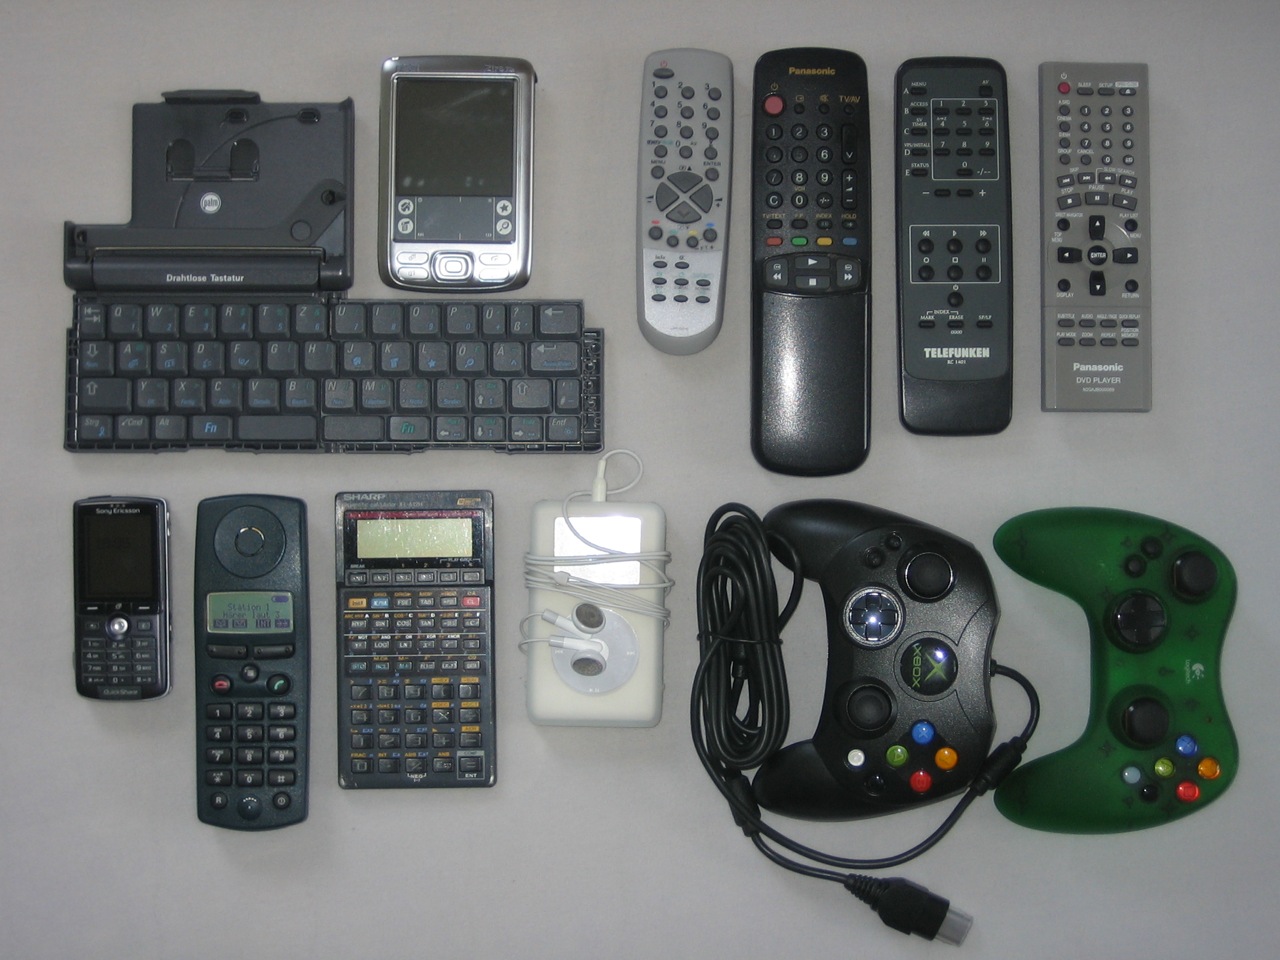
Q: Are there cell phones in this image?
A: Yes, there is a cell phone.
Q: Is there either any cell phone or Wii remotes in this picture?
A: Yes, there is a cell phone.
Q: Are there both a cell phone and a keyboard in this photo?
A: Yes, there are both a cell phone and a keyboard.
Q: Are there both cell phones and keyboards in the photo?
A: Yes, there are both a cell phone and a keyboard.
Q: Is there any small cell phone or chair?
A: Yes, there is a small cell phone.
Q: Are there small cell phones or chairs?
A: Yes, there is a small cell phone.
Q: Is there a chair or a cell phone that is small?
A: Yes, the cell phone is small.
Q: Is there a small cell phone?
A: Yes, there is a small cell phone.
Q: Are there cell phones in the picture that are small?
A: Yes, there is a cell phone that is small.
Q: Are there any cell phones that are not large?
A: Yes, there is a small cell phone.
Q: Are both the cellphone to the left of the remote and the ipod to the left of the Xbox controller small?
A: Yes, both the cell phone and the ipod are small.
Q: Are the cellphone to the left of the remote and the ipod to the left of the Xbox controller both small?
A: Yes, both the cell phone and the ipod are small.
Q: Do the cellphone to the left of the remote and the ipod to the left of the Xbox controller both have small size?
A: Yes, both the cell phone and the ipod are small.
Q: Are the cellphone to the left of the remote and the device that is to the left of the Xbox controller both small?
A: Yes, both the cell phone and the ipod are small.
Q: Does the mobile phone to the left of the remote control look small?
A: Yes, the mobile phone is small.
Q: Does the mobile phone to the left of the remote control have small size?
A: Yes, the mobile phone is small.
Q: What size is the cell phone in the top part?
A: The cellphone is small.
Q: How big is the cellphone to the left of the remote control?
A: The cell phone is small.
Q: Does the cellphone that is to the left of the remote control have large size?
A: No, the cellphone is small.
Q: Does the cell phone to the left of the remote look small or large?
A: The mobile phone is small.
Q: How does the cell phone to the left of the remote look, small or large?
A: The mobile phone is small.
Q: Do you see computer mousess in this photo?
A: No, there are no computer mousess.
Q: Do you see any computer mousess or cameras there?
A: No, there are no computer mousess or cameras.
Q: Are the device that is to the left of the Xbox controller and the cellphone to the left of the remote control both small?
A: Yes, both the ipod and the cellphone are small.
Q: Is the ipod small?
A: Yes, the ipod is small.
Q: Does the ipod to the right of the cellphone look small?
A: Yes, the ipod is small.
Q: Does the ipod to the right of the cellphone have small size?
A: Yes, the ipod is small.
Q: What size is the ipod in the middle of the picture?
A: The ipod is small.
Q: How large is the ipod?
A: The ipod is small.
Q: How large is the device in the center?
A: The ipod is small.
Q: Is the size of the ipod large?
A: No, the ipod is small.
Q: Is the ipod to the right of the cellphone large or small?
A: The ipod is small.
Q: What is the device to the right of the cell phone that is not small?
A: The device is an ipod.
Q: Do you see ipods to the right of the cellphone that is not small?
A: Yes, there is an ipod to the right of the mobile phone.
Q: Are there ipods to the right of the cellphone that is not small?
A: Yes, there is an ipod to the right of the mobile phone.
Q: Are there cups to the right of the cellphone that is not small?
A: No, there is an ipod to the right of the cell phone.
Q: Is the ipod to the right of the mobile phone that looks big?
A: Yes, the ipod is to the right of the cell phone.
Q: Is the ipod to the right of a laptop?
A: No, the ipod is to the right of the cell phone.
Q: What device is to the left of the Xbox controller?
A: The device is an ipod.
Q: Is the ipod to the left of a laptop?
A: No, the ipod is to the left of the Xbox controller.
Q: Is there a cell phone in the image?
A: Yes, there is a cell phone.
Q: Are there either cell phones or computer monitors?
A: Yes, there is a cell phone.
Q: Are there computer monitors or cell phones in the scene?
A: Yes, there is a cell phone.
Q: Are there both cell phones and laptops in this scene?
A: No, there is a cell phone but no laptops.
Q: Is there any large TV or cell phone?
A: Yes, there is a large cell phone.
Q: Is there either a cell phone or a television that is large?
A: Yes, the cell phone is large.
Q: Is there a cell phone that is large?
A: Yes, there is a large cell phone.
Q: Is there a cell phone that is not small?
A: Yes, there is a large cell phone.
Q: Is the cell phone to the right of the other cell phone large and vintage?
A: Yes, the cellphone is large and vintage.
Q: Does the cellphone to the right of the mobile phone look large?
A: Yes, the cell phone is large.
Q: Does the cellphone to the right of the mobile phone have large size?
A: Yes, the cell phone is large.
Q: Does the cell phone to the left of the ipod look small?
A: No, the cellphone is large.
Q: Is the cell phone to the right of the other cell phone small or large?
A: The mobile phone is large.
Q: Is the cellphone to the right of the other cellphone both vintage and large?
A: Yes, the mobile phone is vintage and large.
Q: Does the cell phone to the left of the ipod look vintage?
A: Yes, the mobile phone is vintage.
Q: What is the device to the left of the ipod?
A: The device is a cell phone.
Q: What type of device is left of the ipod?
A: The device is a cell phone.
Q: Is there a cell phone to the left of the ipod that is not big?
A: Yes, there is a cell phone to the left of the ipod.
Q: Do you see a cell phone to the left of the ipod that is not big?
A: Yes, there is a cell phone to the left of the ipod.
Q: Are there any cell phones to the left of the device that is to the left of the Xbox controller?
A: Yes, there is a cell phone to the left of the ipod.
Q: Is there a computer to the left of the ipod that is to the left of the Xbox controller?
A: No, there is a cell phone to the left of the ipod.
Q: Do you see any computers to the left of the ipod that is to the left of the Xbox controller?
A: No, there is a cell phone to the left of the ipod.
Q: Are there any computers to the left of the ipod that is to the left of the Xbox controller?
A: No, there is a cell phone to the left of the ipod.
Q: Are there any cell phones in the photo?
A: Yes, there is a cell phone.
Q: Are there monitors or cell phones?
A: Yes, there is a cell phone.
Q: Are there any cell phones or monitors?
A: Yes, there is a cell phone.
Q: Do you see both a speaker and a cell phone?
A: No, there is a cell phone but no speakers.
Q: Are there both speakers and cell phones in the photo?
A: No, there is a cell phone but no speakers.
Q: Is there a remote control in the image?
A: Yes, there is a remote control.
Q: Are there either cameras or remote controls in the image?
A: Yes, there is a remote control.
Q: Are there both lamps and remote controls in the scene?
A: No, there is a remote control but no lamps.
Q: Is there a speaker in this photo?
A: No, there are no speakers.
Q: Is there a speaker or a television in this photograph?
A: No, there are no speakers or televisions.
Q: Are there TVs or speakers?
A: No, there are no speakers or tvs.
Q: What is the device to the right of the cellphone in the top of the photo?
A: The device is a remote control.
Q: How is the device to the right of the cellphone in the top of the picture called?
A: The device is a remote control.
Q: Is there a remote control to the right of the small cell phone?
A: Yes, there is a remote control to the right of the mobile phone.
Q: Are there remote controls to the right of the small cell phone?
A: Yes, there is a remote control to the right of the mobile phone.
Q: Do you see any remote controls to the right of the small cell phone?
A: Yes, there is a remote control to the right of the mobile phone.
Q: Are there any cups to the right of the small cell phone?
A: No, there is a remote control to the right of the mobile phone.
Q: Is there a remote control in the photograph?
A: Yes, there is a remote control.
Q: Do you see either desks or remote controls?
A: Yes, there is a remote control.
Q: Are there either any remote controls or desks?
A: Yes, there is a remote control.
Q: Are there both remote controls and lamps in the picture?
A: No, there is a remote control but no lamps.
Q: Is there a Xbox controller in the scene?
A: Yes, there is a Xbox controller.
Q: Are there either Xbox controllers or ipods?
A: Yes, there is a Xbox controller.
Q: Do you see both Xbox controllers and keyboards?
A: Yes, there are both a Xbox controller and a keyboard.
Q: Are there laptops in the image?
A: No, there are no laptops.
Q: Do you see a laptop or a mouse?
A: No, there are no laptops or computer mice.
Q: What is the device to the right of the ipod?
A: The device is a Xbox controller.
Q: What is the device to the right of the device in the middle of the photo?
A: The device is a Xbox controller.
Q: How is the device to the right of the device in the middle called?
A: The device is a Xbox controller.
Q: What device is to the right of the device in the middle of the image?
A: The device is a Xbox controller.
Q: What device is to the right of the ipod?
A: The device is a Xbox controller.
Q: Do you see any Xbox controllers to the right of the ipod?
A: Yes, there is a Xbox controller to the right of the ipod.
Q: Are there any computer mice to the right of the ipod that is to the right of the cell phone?
A: No, there is a Xbox controller to the right of the ipod.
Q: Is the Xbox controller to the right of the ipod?
A: Yes, the Xbox controller is to the right of the ipod.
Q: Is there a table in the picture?
A: Yes, there is a table.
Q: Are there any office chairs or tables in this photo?
A: Yes, there is a table.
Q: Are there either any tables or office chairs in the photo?
A: Yes, there is a table.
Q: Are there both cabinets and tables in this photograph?
A: No, there is a table but no cabinets.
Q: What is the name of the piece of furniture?
A: The piece of furniture is a table.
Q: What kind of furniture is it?
A: The piece of furniture is a table.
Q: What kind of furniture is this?
A: This is a table.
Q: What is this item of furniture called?
A: This is a table.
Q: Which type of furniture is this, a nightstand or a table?
A: This is a table.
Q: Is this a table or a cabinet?
A: This is a table.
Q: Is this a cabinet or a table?
A: This is a table.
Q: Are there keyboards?
A: Yes, there is a keyboard.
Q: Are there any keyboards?
A: Yes, there is a keyboard.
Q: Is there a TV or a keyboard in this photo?
A: Yes, there is a keyboard.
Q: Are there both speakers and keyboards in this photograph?
A: No, there is a keyboard but no speakers.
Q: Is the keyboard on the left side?
A: Yes, the keyboard is on the left of the image.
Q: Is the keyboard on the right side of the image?
A: No, the keyboard is on the left of the image.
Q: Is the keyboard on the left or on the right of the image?
A: The keyboard is on the left of the image.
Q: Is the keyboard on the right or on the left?
A: The keyboard is on the left of the image.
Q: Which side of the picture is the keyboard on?
A: The keyboard is on the left of the image.